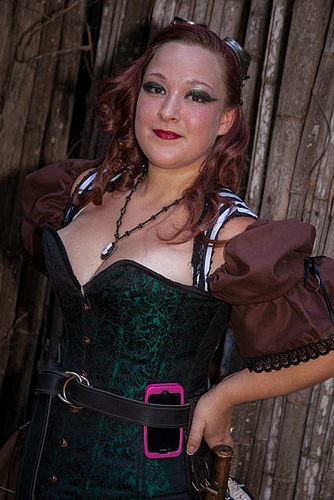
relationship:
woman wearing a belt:
[6, 23, 332, 500] [18, 367, 202, 499]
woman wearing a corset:
[6, 23, 332, 500] [35, 229, 230, 500]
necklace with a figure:
[97, 164, 191, 259] [103, 242, 117, 256]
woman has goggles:
[6, 23, 332, 500] [170, 14, 254, 74]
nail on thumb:
[187, 449, 194, 457] [187, 419, 203, 455]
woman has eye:
[6, 23, 332, 500] [188, 90, 206, 103]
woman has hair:
[6, 23, 332, 500] [89, 25, 247, 229]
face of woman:
[134, 41, 220, 169] [6, 23, 332, 500]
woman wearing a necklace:
[6, 23, 332, 500] [97, 164, 191, 259]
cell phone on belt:
[144, 384, 183, 459] [18, 367, 202, 499]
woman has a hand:
[6, 23, 332, 500] [187, 386, 237, 460]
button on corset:
[78, 302, 88, 311] [35, 229, 230, 500]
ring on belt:
[54, 369, 83, 402] [18, 367, 202, 499]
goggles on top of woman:
[170, 14, 254, 74] [6, 23, 332, 500]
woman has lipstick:
[6, 23, 332, 500] [155, 129, 180, 142]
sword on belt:
[192, 444, 234, 498] [18, 367, 202, 499]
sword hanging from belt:
[192, 444, 234, 498] [18, 367, 202, 499]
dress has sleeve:
[14, 158, 333, 500] [208, 221, 333, 375]